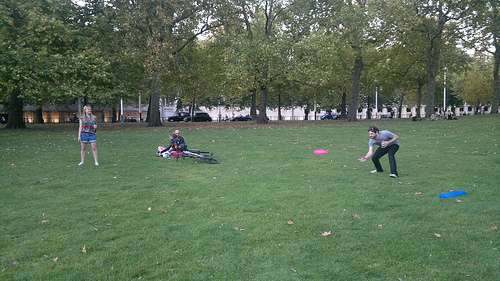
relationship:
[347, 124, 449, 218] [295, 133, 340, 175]
man catching frisbee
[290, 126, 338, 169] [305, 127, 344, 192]
frisbee in air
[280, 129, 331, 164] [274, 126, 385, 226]
frisbee in air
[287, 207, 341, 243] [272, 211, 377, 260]
leaves on ground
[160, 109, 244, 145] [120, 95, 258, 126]
vehicles on street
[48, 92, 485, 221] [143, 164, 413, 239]
people on lawn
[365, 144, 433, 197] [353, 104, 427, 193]
pants on man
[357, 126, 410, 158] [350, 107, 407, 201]
shirt on man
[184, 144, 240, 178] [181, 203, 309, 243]
bike on ground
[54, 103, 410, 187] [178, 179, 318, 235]
people in park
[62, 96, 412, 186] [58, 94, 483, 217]
people playing game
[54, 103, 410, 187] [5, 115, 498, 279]
people in grass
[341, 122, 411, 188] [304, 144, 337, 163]
person catching frisbee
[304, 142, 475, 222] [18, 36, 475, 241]
frisbees in air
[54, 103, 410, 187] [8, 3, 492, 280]
people in day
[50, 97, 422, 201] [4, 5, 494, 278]
people in daytime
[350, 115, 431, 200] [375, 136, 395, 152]
he holding drink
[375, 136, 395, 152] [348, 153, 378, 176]
drink in hand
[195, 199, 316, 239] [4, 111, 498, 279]
patch of field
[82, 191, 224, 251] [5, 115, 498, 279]
patch of grass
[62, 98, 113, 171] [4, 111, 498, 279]
girl in field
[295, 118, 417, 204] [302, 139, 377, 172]
person catching frisbee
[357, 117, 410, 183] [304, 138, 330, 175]
person catching frisbee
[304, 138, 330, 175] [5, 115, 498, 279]
frisbee in grass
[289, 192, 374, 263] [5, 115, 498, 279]
leaves and grass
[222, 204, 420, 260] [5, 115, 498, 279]
leaves and grass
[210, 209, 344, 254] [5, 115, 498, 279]
patch of grass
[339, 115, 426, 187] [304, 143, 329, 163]
guy playing frisbee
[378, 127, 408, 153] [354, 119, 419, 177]
arm of man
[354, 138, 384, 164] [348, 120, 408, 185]
arm of man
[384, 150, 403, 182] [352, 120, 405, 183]
legs of man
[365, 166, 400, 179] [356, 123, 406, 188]
shoes of man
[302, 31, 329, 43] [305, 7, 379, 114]
leaves of tree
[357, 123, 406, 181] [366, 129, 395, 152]
man wearing shirt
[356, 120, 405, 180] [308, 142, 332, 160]
person playing with frisbee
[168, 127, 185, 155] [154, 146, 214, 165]
person sitting next to bicycle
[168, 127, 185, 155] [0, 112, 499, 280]
person sitting on ground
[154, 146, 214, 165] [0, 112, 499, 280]
bicycle laying on ground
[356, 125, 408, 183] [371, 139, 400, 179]
man wearing pants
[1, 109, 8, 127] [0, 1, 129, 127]
dumpster behind tree